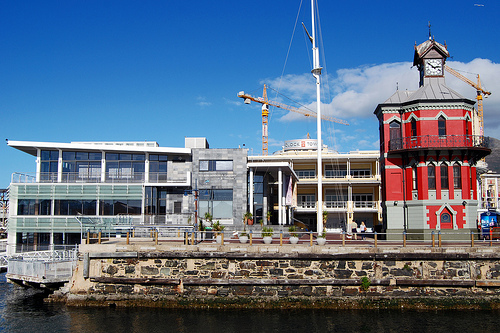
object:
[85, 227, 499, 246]
fence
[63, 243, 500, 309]
wall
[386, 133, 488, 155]
balcony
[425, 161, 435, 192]
window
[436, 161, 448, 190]
window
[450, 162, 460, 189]
window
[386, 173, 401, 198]
red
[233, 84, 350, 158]
crane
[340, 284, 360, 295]
stone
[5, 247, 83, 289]
boat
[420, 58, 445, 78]
clock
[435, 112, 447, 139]
window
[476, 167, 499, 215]
building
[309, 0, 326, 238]
white mast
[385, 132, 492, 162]
observation deck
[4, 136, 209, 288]
building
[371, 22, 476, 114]
roof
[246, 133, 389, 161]
roof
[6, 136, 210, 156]
roof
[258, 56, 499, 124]
cloud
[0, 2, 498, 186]
sky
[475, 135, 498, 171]
mountain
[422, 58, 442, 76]
face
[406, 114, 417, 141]
window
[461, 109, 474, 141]
window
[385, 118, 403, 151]
window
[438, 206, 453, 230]
window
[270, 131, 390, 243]
building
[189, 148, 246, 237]
building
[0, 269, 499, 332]
water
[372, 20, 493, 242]
building